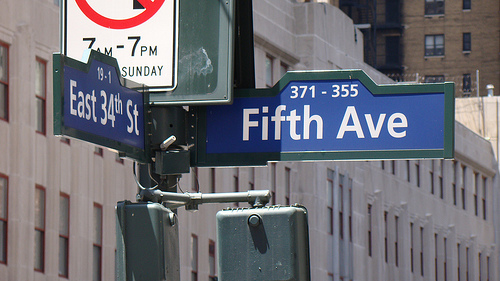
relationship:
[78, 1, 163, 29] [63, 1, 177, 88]
circle on background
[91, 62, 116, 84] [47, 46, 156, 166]
numbers on sign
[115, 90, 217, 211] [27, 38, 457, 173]
pole holding street signs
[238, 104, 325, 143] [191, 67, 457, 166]
print on blue sign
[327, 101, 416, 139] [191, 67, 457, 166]
print on blue sign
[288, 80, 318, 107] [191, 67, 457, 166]
white print on blue sign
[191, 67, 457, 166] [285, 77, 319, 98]
blue sign reading 371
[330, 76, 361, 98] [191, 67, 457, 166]
white print on a blue sign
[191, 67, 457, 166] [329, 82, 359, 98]
blue sign reading 355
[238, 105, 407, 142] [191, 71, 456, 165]
white print on a blue sign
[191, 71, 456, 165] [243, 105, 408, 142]
blue sign reading fifth ave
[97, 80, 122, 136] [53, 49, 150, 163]
white print on sign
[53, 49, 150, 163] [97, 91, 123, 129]
sign reading 34th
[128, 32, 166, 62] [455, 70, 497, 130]
black print on sign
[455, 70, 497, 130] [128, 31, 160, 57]
sign reading 7pm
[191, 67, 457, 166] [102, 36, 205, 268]
blue sign attached to post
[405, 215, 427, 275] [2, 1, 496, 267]
windows on building